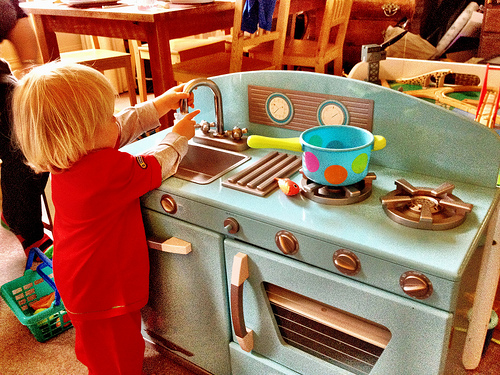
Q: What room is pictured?
A: It is a kitchen.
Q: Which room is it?
A: It is a kitchen.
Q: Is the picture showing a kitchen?
A: Yes, it is showing a kitchen.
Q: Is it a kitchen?
A: Yes, it is a kitchen.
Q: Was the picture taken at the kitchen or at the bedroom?
A: It was taken at the kitchen.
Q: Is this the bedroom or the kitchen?
A: It is the kitchen.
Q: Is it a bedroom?
A: No, it is a kitchen.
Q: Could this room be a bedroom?
A: No, it is a kitchen.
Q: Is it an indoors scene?
A: Yes, it is indoors.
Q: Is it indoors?
A: Yes, it is indoors.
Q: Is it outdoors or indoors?
A: It is indoors.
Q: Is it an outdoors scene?
A: No, it is indoors.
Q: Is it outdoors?
A: No, it is indoors.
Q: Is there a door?
A: Yes, there is a door.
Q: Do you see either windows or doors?
A: Yes, there is a door.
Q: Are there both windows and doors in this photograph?
A: No, there is a door but no windows.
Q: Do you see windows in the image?
A: No, there are no windows.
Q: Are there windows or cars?
A: No, there are no windows or cars.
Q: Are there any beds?
A: No, there are no beds.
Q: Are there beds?
A: No, there are no beds.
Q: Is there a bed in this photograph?
A: No, there are no beds.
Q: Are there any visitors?
A: No, there are no visitors.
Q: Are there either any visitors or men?
A: No, there are no visitors or men.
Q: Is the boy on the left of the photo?
A: Yes, the boy is on the left of the image.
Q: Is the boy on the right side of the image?
A: No, the boy is on the left of the image.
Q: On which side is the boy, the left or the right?
A: The boy is on the left of the image.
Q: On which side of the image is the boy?
A: The boy is on the left of the image.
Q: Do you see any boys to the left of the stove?
A: Yes, there is a boy to the left of the stove.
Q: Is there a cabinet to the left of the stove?
A: No, there is a boy to the left of the stove.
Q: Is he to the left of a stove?
A: Yes, the boy is to the left of a stove.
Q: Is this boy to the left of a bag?
A: No, the boy is to the left of a stove.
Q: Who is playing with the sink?
A: The boy is playing with the sink.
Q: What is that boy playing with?
A: The boy is playing with a sink.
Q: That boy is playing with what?
A: The boy is playing with a sink.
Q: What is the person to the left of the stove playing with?
A: The boy is playing with a sink.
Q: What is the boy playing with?
A: The boy is playing with a sink.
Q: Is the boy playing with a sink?
A: Yes, the boy is playing with a sink.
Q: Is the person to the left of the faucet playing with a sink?
A: Yes, the boy is playing with a sink.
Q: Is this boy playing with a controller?
A: No, the boy is playing with a sink.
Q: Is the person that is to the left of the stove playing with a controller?
A: No, the boy is playing with a sink.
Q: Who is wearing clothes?
A: The boy is wearing clothes.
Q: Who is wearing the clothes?
A: The boy is wearing clothes.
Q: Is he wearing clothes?
A: Yes, the boy is wearing clothes.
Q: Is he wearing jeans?
A: No, the boy is wearing clothes.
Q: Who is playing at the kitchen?
A: The boy is playing at the kitchen.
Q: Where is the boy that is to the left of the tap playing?
A: The boy is playing at the kitchen.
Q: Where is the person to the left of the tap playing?
A: The boy is playing at the kitchen.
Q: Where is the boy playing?
A: The boy is playing at the kitchen.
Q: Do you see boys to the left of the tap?
A: Yes, there is a boy to the left of the tap.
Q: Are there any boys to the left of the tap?
A: Yes, there is a boy to the left of the tap.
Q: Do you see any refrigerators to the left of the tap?
A: No, there is a boy to the left of the tap.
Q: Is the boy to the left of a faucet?
A: Yes, the boy is to the left of a faucet.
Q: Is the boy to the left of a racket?
A: No, the boy is to the left of a faucet.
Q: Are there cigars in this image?
A: No, there are no cigars.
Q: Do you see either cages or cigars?
A: No, there are no cigars or cages.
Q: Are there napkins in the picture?
A: No, there are no napkins.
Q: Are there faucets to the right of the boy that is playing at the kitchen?
A: Yes, there is a faucet to the right of the boy.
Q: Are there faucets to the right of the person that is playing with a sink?
A: Yes, there is a faucet to the right of the boy.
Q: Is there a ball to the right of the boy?
A: No, there is a faucet to the right of the boy.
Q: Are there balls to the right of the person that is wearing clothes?
A: No, there is a faucet to the right of the boy.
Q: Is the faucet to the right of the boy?
A: Yes, the faucet is to the right of the boy.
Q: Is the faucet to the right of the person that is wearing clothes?
A: Yes, the faucet is to the right of the boy.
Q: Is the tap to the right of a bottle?
A: No, the tap is to the right of the boy.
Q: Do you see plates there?
A: No, there are no plates.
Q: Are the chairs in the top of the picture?
A: Yes, the chairs are in the top of the image.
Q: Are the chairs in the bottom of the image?
A: No, the chairs are in the top of the image.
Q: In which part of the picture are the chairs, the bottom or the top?
A: The chairs are in the top of the image.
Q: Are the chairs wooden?
A: Yes, the chairs are wooden.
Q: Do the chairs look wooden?
A: Yes, the chairs are wooden.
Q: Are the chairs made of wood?
A: Yes, the chairs are made of wood.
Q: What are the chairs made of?
A: The chairs are made of wood.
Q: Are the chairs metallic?
A: No, the chairs are wooden.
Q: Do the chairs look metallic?
A: No, the chairs are wooden.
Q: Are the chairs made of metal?
A: No, the chairs are made of wood.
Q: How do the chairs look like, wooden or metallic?
A: The chairs are wooden.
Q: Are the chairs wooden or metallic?
A: The chairs are wooden.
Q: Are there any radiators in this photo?
A: No, there are no radiators.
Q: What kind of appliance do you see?
A: The appliance is a stove.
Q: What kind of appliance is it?
A: The appliance is a stove.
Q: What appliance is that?
A: This is a stove.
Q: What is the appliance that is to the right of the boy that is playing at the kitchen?
A: The appliance is a stove.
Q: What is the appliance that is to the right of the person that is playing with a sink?
A: The appliance is a stove.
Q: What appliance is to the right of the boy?
A: The appliance is a stove.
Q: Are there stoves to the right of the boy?
A: Yes, there is a stove to the right of the boy.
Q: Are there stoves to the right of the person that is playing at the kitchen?
A: Yes, there is a stove to the right of the boy.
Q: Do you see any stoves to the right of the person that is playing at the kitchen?
A: Yes, there is a stove to the right of the boy.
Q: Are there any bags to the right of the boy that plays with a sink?
A: No, there is a stove to the right of the boy.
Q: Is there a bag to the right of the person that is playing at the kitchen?
A: No, there is a stove to the right of the boy.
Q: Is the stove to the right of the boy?
A: Yes, the stove is to the right of the boy.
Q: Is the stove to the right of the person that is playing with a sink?
A: Yes, the stove is to the right of the boy.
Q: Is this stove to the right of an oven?
A: No, the stove is to the right of the boy.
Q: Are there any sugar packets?
A: No, there are no sugar packets.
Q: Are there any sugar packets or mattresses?
A: No, there are no sugar packets or mattresses.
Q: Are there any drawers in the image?
A: No, there are no drawers.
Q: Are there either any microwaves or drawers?
A: No, there are no drawers or microwaves.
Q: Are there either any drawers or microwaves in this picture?
A: No, there are no drawers or microwaves.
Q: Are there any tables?
A: Yes, there is a table.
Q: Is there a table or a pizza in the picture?
A: Yes, there is a table.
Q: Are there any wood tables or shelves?
A: Yes, there is a wood table.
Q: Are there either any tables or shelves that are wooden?
A: Yes, the table is wooden.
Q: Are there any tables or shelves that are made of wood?
A: Yes, the table is made of wood.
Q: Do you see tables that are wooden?
A: Yes, there is a wood table.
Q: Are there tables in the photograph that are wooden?
A: Yes, there is a wood table.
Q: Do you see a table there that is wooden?
A: Yes, there is a table that is wooden.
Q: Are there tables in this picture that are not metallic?
A: Yes, there is a wooden table.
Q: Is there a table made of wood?
A: Yes, there is a table that is made of wood.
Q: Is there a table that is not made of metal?
A: Yes, there is a table that is made of wood.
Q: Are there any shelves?
A: No, there are no shelves.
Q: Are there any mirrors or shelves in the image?
A: No, there are no shelves or mirrors.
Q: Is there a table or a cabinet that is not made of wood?
A: No, there is a table but it is made of wood.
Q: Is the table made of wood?
A: Yes, the table is made of wood.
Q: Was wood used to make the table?
A: Yes, the table is made of wood.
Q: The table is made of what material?
A: The table is made of wood.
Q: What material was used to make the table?
A: The table is made of wood.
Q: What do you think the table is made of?
A: The table is made of wood.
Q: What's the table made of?
A: The table is made of wood.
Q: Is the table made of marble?
A: No, the table is made of wood.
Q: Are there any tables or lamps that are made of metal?
A: No, there is a table but it is made of wood.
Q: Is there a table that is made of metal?
A: No, there is a table but it is made of wood.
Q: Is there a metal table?
A: No, there is a table but it is made of wood.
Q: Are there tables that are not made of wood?
A: No, there is a table but it is made of wood.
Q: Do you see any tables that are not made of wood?
A: No, there is a table but it is made of wood.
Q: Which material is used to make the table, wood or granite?
A: The table is made of wood.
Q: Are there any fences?
A: No, there are no fences.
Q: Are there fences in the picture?
A: No, there are no fences.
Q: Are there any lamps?
A: No, there are no lamps.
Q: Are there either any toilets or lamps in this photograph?
A: No, there are no lamps or toilets.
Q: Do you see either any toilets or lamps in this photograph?
A: No, there are no lamps or toilets.